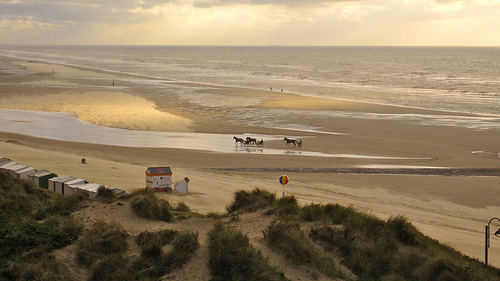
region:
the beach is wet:
[201, 41, 482, 195]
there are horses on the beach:
[201, 129, 313, 151]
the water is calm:
[193, 27, 450, 84]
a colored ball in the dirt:
[267, 168, 290, 188]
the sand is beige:
[83, 133, 208, 210]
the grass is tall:
[220, 187, 434, 263]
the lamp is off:
[470, 207, 498, 270]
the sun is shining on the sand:
[60, 72, 188, 135]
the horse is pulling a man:
[271, 127, 313, 152]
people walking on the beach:
[252, 70, 297, 102]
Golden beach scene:
[9, 7, 494, 269]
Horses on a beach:
[227, 128, 331, 168]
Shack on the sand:
[139, 158, 211, 211]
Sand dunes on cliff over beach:
[8, 191, 468, 278]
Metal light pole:
[476, 203, 499, 262]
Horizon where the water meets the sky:
[3, 39, 493, 62]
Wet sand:
[16, 99, 495, 157]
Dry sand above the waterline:
[46, 169, 228, 205]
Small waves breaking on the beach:
[58, 51, 267, 89]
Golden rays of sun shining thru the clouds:
[59, 4, 379, 54]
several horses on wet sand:
[216, 123, 309, 158]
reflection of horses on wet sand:
[224, 140, 310, 162]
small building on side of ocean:
[0, 150, 195, 221]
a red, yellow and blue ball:
[276, 166, 295, 200]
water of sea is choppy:
[3, 31, 498, 132]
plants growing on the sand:
[2, 179, 482, 279]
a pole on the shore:
[467, 210, 498, 278]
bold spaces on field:
[37, 211, 351, 278]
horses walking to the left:
[222, 126, 309, 156]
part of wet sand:
[1, 121, 201, 158]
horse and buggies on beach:
[191, 108, 312, 160]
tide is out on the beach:
[34, 54, 492, 175]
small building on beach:
[137, 153, 194, 215]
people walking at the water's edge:
[261, 83, 291, 102]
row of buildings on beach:
[4, 158, 119, 203]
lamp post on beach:
[456, 196, 498, 257]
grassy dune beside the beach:
[26, 193, 412, 271]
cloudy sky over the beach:
[10, 6, 490, 51]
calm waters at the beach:
[26, 37, 478, 122]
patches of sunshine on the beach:
[26, 78, 364, 143]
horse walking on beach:
[281, 136, 303, 149]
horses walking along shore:
[231, 135, 263, 147]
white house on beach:
[143, 164, 173, 194]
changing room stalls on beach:
[6, 158, 128, 208]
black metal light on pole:
[484, 213, 499, 263]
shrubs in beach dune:
[34, 211, 409, 279]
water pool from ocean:
[4, 113, 441, 174]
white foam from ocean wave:
[158, 68, 498, 97]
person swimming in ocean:
[268, 84, 273, 93]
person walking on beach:
[111, 79, 115, 85]